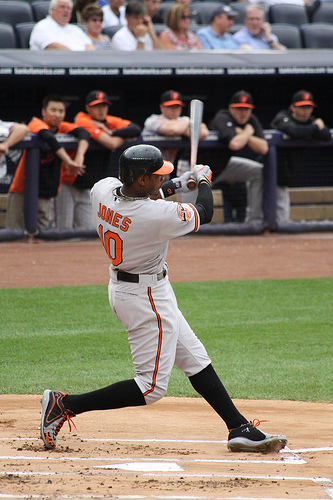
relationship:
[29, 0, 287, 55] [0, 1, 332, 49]
spectators in stands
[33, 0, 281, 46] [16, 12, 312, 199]
spectators sitting in bleachers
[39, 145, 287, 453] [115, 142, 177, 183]
man wearing hat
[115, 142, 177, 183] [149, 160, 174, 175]
hat with visor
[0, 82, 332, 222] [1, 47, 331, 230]
men standing in dugout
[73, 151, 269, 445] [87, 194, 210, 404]
man wearing uniform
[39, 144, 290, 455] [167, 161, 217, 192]
man wearing gloves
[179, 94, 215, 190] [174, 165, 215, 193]
bat in man's hands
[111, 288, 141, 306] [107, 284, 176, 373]
pocket in pants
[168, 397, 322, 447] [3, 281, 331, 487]
turf on baseball field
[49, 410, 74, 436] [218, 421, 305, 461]
shoe laces on cleat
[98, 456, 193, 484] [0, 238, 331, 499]
home plate on a baseball field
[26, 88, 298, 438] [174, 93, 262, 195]
baseball player swings a bat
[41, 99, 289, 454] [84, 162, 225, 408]
baseball player wearing uniform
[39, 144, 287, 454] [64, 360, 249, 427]
man wearing socks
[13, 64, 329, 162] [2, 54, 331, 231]
baseball player in batters box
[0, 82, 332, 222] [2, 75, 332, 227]
men in dugout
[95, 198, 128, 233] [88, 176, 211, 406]
letters on a baseball uniform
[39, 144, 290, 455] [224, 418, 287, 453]
man wearing shoe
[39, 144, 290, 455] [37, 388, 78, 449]
man wearing shoe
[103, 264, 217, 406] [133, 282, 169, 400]
pants with stripe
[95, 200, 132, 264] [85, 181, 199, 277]
writing on jersey